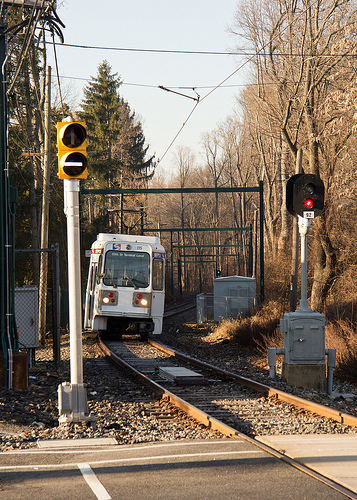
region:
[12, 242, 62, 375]
A chain link fence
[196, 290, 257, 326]
A chain link fence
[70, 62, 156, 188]
A large, tall tree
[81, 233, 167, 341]
A large white train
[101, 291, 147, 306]
A pair of headlights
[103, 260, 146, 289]
A pair of windshield wipers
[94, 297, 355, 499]
A set of railroad tracks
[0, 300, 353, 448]
some gravel on the ground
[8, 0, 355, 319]
A large wooded area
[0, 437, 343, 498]
an asphalt road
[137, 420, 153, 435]
Small grey pepples in the ground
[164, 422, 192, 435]
Small grey pepples in the ground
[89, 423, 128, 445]
Small grey pepples in the ground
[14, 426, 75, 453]
Small grey pepples in the ground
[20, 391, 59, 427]
Small grey pepples in the ground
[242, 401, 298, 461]
Small grey pepples in the ground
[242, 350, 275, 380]
Small grey pepples in the ground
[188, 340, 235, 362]
Small grey pepples in the ground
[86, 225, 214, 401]
Train on the tracks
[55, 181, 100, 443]
Silver post on the ground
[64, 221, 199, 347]
white train on rails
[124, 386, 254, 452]
rusted steel railroad tracks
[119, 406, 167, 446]
gray gravel between tracks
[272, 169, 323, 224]
red railroad signal on right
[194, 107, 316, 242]
tall brown trees by tracks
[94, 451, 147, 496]
WHITE LINES PAINTED ON ROAD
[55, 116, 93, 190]
YELLOW SIGNAL ON SIDE OF ROAD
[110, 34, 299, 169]
ELECTRIC LINES ABOVE TRAIN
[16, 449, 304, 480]
SHADOWS OF POLES ON ROAD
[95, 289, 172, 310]
ILLUMINATED HEADLIGHTS ON TRAIN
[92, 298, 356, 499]
A set of train tracks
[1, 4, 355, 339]
a large wooded area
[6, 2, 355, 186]
A clear blue sky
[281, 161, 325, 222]
the light is red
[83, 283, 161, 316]
the headlights are on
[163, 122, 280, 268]
the trees are bare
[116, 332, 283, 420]
a shadow on the tracks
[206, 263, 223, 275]
the light is green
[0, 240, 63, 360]
a fence behind the traffic light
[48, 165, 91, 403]
the pole is grey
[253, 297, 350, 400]
the grass is high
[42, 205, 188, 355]
the train is in motion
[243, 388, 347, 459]
the sun on the tracks